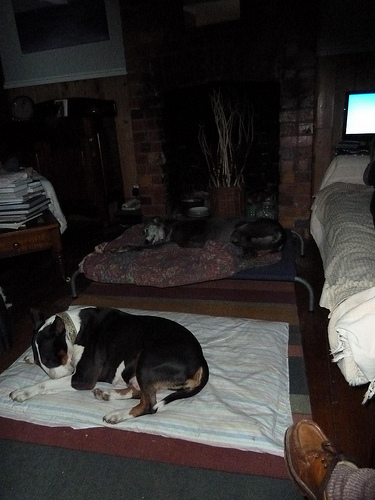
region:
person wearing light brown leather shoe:
[281, 410, 354, 499]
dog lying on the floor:
[7, 298, 212, 441]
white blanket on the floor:
[1, 296, 295, 459]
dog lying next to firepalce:
[115, 210, 291, 264]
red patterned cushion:
[79, 212, 293, 295]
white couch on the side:
[312, 141, 373, 393]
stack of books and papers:
[0, 157, 68, 242]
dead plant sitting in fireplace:
[190, 85, 259, 224]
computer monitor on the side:
[338, 86, 372, 143]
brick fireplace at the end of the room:
[113, 1, 319, 235]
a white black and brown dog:
[8, 307, 207, 425]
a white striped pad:
[0, 306, 294, 458]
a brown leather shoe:
[283, 420, 350, 498]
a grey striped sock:
[328, 461, 374, 498]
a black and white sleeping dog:
[111, 215, 304, 262]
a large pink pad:
[82, 223, 283, 284]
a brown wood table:
[0, 208, 68, 311]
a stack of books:
[0, 169, 51, 229]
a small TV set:
[344, 91, 374, 139]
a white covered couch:
[308, 159, 373, 395]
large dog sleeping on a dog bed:
[23, 302, 218, 428]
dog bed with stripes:
[202, 297, 284, 456]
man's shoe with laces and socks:
[272, 411, 373, 497]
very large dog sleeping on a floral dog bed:
[94, 211, 286, 284]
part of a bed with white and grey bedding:
[301, 152, 374, 363]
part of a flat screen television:
[330, 76, 373, 147]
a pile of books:
[1, 158, 52, 220]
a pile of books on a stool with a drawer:
[4, 155, 65, 293]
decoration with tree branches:
[188, 90, 250, 215]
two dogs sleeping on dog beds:
[14, 178, 301, 441]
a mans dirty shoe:
[283, 405, 322, 443]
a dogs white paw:
[14, 375, 37, 401]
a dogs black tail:
[165, 386, 195, 416]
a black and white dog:
[143, 343, 177, 372]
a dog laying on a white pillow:
[239, 418, 285, 463]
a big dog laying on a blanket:
[147, 214, 168, 241]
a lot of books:
[18, 183, 41, 210]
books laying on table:
[12, 192, 41, 220]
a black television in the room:
[338, 109, 360, 142]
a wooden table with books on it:
[37, 219, 70, 246]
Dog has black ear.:
[49, 318, 74, 339]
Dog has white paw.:
[8, 378, 48, 411]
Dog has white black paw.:
[93, 412, 142, 430]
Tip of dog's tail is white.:
[147, 392, 190, 429]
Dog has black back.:
[141, 315, 208, 377]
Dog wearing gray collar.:
[54, 310, 88, 351]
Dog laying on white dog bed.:
[28, 292, 232, 429]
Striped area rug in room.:
[252, 294, 315, 381]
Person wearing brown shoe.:
[270, 417, 328, 468]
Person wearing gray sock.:
[328, 457, 354, 491]